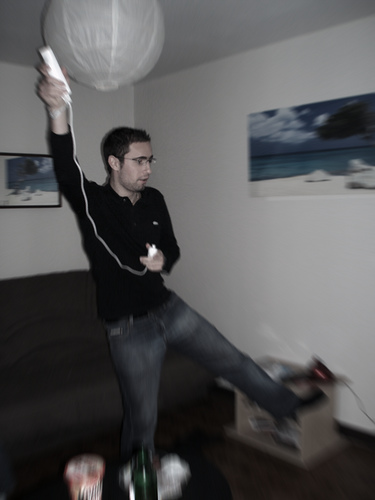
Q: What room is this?
A: Living room.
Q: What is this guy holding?
A: Game controlers.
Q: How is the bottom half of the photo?
A: Blurry.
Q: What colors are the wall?
A: White.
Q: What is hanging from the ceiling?
A: A white ball.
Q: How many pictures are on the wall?
A: 2.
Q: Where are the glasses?
A: On the mans head.